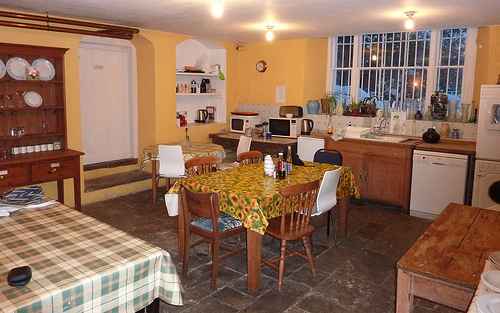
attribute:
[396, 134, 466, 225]
washer — BOTTOM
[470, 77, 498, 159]
dryer — SITTING , TOP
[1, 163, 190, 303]
tablecloth — green and white, checkered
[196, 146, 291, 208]
tablecloth — floral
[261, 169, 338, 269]
chairs — wood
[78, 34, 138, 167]
door — white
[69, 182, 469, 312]
floor — dark gray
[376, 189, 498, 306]
table — wood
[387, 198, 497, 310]
table — wooden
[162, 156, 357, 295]
table — wooden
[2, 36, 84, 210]
hutch — wooden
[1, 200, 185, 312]
table clothe — white and grey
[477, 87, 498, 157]
washer — stacked 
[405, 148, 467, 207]
dishwasher — white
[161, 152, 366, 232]
table cloth — sunflower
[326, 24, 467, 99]
window — white trimmed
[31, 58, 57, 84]
plate — white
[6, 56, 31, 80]
plate — white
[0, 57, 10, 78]
plate — white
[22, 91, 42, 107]
plate — white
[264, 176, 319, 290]
chair — wood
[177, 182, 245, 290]
chair — wood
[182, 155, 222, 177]
chair — wood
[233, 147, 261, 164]
chair — wood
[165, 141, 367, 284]
chairs — wooden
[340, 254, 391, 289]
tile — grey 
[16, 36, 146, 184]
doorway — WHITE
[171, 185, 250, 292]
chair — brown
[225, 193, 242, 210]
flower — yellow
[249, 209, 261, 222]
flower — yellow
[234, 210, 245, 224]
flower — yellow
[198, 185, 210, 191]
flower — yellow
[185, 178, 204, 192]
flower — yellow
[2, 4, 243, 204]
wall — yellow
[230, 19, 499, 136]
wall — yellow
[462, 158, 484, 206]
dryer — stacked 